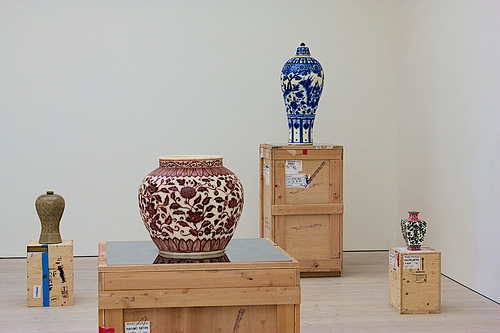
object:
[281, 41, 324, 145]
vase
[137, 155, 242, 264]
vase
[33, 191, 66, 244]
vase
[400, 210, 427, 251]
vase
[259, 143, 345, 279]
crate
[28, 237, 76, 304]
crate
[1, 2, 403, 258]
wall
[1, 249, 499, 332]
floor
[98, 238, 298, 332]
crate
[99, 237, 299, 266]
surface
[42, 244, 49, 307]
stripe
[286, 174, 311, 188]
sticker